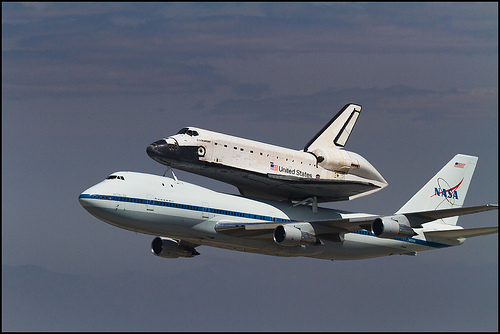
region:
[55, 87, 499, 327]
The shuttle being taken back to its base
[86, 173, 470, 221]
this is a nasa jet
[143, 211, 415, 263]
the jet engines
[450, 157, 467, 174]
the american flag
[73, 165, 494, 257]
this plane is white with a blue stripe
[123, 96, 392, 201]
the shuttle is black & white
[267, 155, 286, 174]
the american flag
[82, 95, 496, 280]
the space shuttles rides piggyback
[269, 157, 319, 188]
united states is written on the side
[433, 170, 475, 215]
Nasa is written on the tail of the jet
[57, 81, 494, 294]
a small plane over a big one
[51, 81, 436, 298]
a small plane over a big one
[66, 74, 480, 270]
a small plane over a big one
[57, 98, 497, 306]
a small plane over a big one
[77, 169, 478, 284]
the plane is light blue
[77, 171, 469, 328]
the plane is light blue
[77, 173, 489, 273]
the plane is light blue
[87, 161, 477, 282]
the plane is light blue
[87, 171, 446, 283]
the plane is light blue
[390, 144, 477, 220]
the NASA logo on a plane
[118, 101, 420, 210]
a United State's space shuttle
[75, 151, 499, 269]
a blue plane with the NASA logo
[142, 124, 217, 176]
the cockpit of a space shuttle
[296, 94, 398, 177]
the tail of a space shuttle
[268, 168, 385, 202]
the wing of a space shuttle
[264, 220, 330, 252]
the engine of a white blue plane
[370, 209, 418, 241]
the engine of a white blue plane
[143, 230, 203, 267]
the engine of a white blue plane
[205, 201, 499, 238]
the wing of a plane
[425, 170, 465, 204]
nasa on the plane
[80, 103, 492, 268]
planes in the sky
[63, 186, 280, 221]
stripe on the plane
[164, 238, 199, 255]
engine of the plane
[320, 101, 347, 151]
tail of hte plane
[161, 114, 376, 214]
shuttle on the plane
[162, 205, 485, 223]
wing of the plane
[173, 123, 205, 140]
windshield on the shuttle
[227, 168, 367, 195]
wing of the shuttle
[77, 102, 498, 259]
Space shuttle riding on the back of a 747 Jumbo Jet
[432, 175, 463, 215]
NASA logo on tail of Jumbo airplane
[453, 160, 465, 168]
United States flag on tail of Jumbo jet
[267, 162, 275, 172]
United States flag on side of space shuttle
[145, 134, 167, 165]
Black nose of a space shuttle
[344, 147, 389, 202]
Rear space shuttle engines with cover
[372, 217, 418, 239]
Jet engine under wing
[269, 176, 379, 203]
Wing of a space shuttle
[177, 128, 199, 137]
Windshield of space shuttle cockpit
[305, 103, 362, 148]
Tail of space shuttle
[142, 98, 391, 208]
White and black airplane saying United States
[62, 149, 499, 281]
White and blue airplane that says NASA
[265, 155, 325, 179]
United States logo with flag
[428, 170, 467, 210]
Red gray and blue NASA logo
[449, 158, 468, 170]
Small American Flag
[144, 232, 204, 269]
Large jet engine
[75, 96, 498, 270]
Two flying planes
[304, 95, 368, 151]
White and black airplane tail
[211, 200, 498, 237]
Large airplane wings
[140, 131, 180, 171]
Small airplane nose.